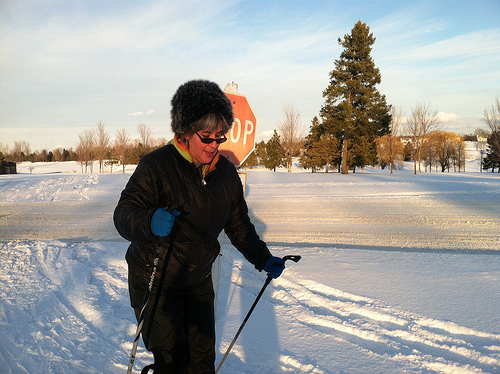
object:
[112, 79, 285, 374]
she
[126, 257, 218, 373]
pants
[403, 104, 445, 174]
tree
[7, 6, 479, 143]
sky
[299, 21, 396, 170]
tree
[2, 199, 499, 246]
road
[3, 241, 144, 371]
tracks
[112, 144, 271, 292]
coat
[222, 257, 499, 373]
tracks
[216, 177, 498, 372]
snow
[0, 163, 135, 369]
snow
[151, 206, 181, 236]
glove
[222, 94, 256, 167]
sign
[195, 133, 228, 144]
sunglasses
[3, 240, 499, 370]
trails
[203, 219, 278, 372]
shade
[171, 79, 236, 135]
hat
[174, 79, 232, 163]
head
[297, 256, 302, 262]
edge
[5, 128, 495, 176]
foreground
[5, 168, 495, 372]
ground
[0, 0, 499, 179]
background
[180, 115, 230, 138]
hair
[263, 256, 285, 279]
glove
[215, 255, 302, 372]
pole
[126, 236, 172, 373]
pole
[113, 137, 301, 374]
skiing gear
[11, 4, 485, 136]
clouds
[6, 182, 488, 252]
street